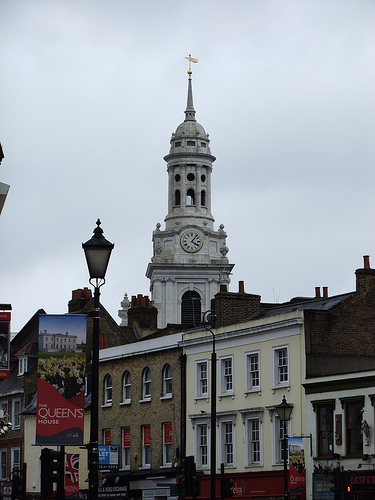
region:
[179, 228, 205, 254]
a clock on the clock tower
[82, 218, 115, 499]
a lamp post on the sidewalk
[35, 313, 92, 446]
an advertising banner on the lamp post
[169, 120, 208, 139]
a dome type roof on the clock tower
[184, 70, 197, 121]
a steeple on the clock tower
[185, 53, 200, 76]
a weather vane on the top of the steeple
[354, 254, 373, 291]
a chimney on the roof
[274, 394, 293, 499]
a street lamp across the street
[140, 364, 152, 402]
arched window frame on the building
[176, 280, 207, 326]
huge archway window on the tower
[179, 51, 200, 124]
Tall steeple with weather vane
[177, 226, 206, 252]
Large clock on side of building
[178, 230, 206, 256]
Analog clock showing 4:05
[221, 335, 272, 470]
Yellow two-story building with white windows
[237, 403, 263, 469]
White window with white stone cornice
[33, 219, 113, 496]
Black street lamp with banner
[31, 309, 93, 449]
Banner ad for The Queen's House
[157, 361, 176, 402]
White arched window in brown building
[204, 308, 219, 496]
Tall arched street lamp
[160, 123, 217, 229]
Tall domed tower with arched windows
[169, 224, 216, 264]
clock on the building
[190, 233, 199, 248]
hands of the clock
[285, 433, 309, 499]
signs on the street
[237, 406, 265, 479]
window of the building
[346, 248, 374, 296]
chimney of the building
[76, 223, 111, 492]
street light on the street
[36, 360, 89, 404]
flowers on the sign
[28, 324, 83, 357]
picture of building on the sign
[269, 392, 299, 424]
shade of the lamp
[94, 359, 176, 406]
curved windows on the building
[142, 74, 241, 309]
clock tower above buildings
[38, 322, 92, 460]
red queens sign by street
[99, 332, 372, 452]
white and brick building fronts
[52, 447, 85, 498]
UK flag by road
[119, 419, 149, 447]
white shades on windows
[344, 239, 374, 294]
chimney on the rooftop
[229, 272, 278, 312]
chimney on the rooftop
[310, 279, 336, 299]
chimneys on the rooftop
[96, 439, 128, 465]
blue sign by road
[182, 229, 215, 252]
roman numerals on clock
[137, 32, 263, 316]
white and gray clock tower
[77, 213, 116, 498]
black and white pole light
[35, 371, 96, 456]
the queens house sign on pole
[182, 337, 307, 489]
yellow house on the street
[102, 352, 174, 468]
gray house on the street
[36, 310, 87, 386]
flag on the light pole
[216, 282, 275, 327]
chimney on the roof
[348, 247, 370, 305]
chimney on the roof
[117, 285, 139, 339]
steeple on a building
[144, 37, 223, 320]
steeple on the top of a building